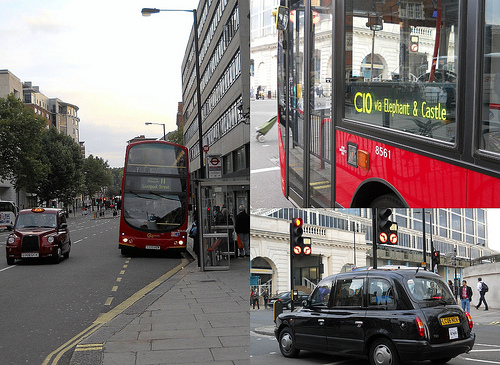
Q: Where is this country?
A: Great Britain.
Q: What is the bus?
A: One is a double decker.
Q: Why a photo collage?
A: Show different scenes.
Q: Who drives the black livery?
A: A paid driver.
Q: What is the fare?
A: Varies as to distance.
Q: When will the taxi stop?
A: At the destination.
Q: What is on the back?
A: The license plate.